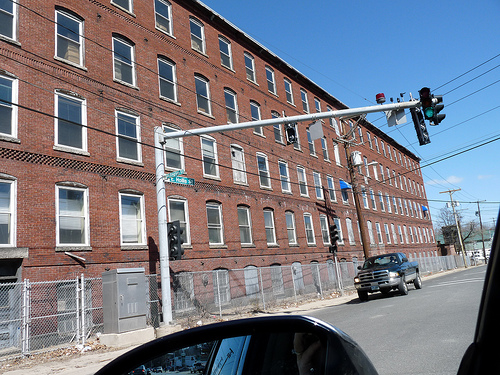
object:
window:
[193, 69, 210, 116]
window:
[224, 89, 239, 124]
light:
[419, 87, 445, 126]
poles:
[448, 191, 469, 268]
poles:
[474, 200, 491, 267]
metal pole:
[152, 126, 174, 326]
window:
[53, 7, 93, 68]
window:
[190, 74, 212, 113]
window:
[112, 31, 140, 89]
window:
[52, 90, 90, 152]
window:
[114, 104, 146, 166]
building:
[0, 1, 440, 356]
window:
[230, 140, 253, 190]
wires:
[424, 52, 500, 166]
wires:
[355, 114, 422, 178]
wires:
[421, 162, 456, 193]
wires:
[482, 202, 497, 222]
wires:
[427, 197, 442, 222]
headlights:
[353, 276, 363, 283]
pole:
[153, 96, 419, 326]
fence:
[1, 253, 478, 357]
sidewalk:
[14, 260, 491, 374]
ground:
[337, 281, 479, 337]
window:
[119, 189, 147, 247]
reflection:
[128, 330, 330, 374]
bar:
[154, 100, 419, 137]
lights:
[410, 104, 431, 146]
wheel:
[412, 273, 422, 289]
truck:
[352, 251, 421, 301]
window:
[255, 150, 275, 190]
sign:
[165, 177, 192, 184]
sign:
[169, 168, 187, 175]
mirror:
[97, 312, 380, 374]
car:
[91, 200, 499, 374]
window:
[115, 113, 142, 164]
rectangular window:
[156, 58, 177, 101]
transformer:
[350, 149, 364, 167]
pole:
[345, 163, 375, 261]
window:
[207, 204, 229, 245]